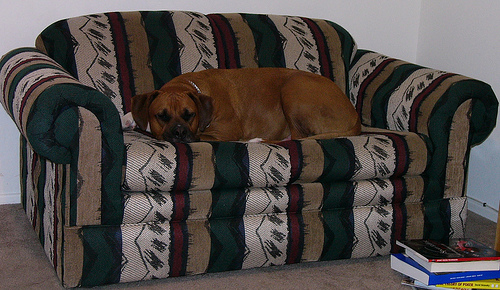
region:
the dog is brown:
[121, 57, 366, 164]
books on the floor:
[393, 187, 475, 287]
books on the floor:
[378, 233, 495, 280]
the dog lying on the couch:
[133, 65, 362, 139]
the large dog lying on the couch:
[131, 65, 361, 140]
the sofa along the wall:
[0, 10, 499, 287]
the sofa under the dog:
[0, 9, 497, 289]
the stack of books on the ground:
[388, 235, 499, 288]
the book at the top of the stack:
[393, 235, 498, 261]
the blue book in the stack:
[389, 252, 499, 286]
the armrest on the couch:
[0, 46, 499, 205]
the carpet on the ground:
[1, 202, 496, 287]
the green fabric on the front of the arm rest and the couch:
[26, 83, 121, 288]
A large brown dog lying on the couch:
[144, 63, 369, 150]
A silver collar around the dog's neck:
[177, 79, 206, 99]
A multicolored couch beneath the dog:
[37, 0, 470, 254]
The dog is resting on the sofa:
[125, 62, 387, 157]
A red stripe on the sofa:
[157, 135, 203, 277]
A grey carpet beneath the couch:
[282, 260, 385, 285]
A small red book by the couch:
[408, 235, 496, 263]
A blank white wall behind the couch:
[385, 16, 481, 58]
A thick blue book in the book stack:
[394, 259, 495, 285]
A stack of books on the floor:
[392, 238, 499, 288]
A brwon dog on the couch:
[134, 65, 361, 150]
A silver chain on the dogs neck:
[185, 77, 202, 90]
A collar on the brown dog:
[186, 79, 203, 91]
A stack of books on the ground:
[385, 238, 498, 288]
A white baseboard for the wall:
[0, 192, 20, 204]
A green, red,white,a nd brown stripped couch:
[0, 17, 499, 285]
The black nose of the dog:
[172, 123, 189, 140]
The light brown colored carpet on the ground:
[207, 273, 382, 287]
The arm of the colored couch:
[0, 46, 65, 143]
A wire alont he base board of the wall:
[468, 193, 498, 220]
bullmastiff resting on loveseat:
[0, 7, 498, 288]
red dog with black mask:
[130, 62, 364, 148]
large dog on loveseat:
[1, 9, 498, 289]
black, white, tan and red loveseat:
[0, 8, 499, 289]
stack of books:
[388, 232, 498, 289]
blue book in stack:
[386, 234, 498, 289]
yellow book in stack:
[412, 279, 498, 288]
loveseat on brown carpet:
[2, 9, 494, 288]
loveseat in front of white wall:
[1, 1, 416, 288]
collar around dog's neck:
[160, 72, 210, 94]